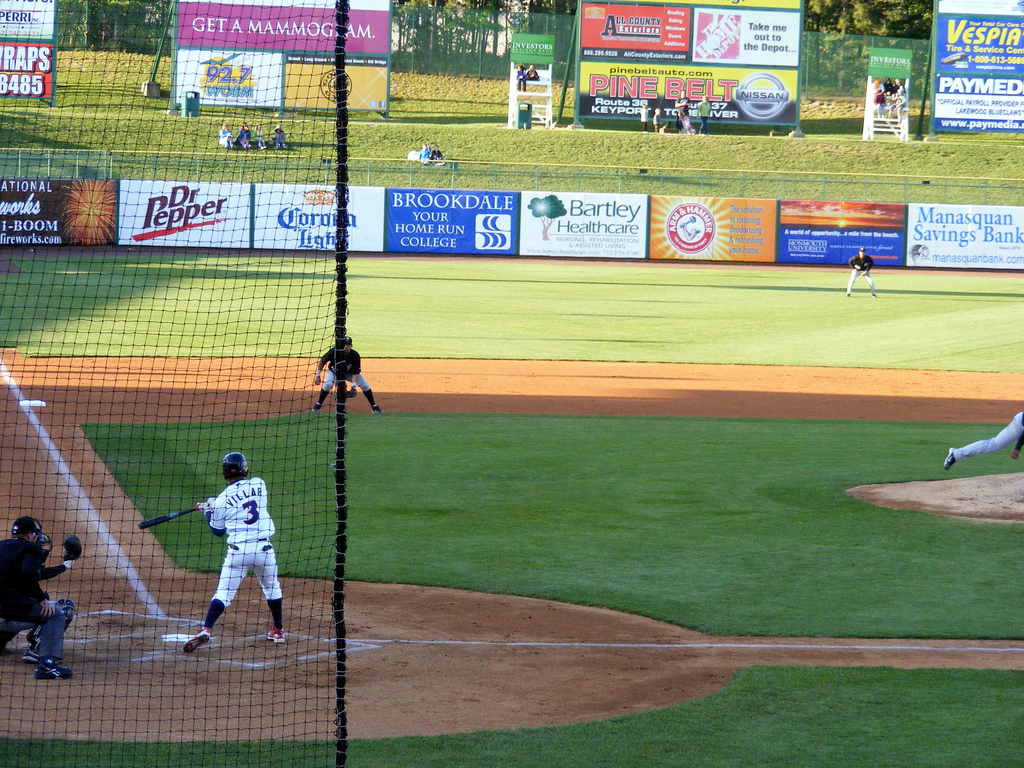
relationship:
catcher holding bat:
[186, 450, 290, 650] [135, 497, 206, 532]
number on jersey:
[241, 500, 259, 524] [208, 477, 276, 544]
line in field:
[375, 636, 1023, 653] [2, 270, 1021, 765]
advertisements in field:
[3, 182, 1022, 278] [2, 270, 1021, 765]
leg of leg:
[944, 408, 1022, 475] [944, 408, 1023, 475]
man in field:
[840, 247, 882, 298] [0, 282, 1022, 378]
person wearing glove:
[3, 513, 84, 680] [59, 525, 86, 576]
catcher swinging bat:
[186, 450, 290, 650] [138, 493, 212, 528]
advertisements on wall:
[3, 182, 1022, 278] [352, 179, 1007, 274]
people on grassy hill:
[175, 92, 328, 166] [175, 92, 328, 166]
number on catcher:
[215, 487, 267, 541] [186, 450, 290, 650]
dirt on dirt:
[311, 336, 382, 414] [289, 318, 411, 446]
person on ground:
[3, 503, 101, 687] [35, 630, 317, 703]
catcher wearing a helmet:
[186, 450, 290, 650] [212, 440, 261, 488]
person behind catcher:
[3, 513, 84, 680] [128, 422, 340, 706]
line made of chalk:
[374, 636, 1020, 653] [55, 463, 142, 569]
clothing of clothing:
[955, 409, 1024, 465] [919, 387, 1019, 502]